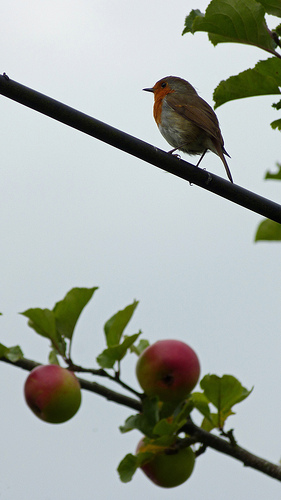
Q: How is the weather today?
A: It is overcast.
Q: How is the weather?
A: It is overcast.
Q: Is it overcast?
A: Yes, it is overcast.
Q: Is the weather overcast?
A: Yes, it is overcast.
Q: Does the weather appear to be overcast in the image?
A: Yes, it is overcast.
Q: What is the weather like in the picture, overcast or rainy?
A: It is overcast.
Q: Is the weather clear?
A: No, it is overcast.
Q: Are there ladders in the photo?
A: No, there are no ladders.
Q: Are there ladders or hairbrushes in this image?
A: No, there are no ladders or hairbrushes.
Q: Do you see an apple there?
A: Yes, there are apples.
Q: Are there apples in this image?
A: Yes, there are apples.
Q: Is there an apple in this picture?
A: Yes, there are apples.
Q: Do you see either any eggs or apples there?
A: Yes, there are apples.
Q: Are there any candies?
A: No, there are no candies.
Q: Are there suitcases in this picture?
A: No, there are no suitcases.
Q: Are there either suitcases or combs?
A: No, there are no suitcases or combs.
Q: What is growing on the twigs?
A: The leaves are growing on the twigs.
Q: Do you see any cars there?
A: No, there are no cars.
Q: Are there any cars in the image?
A: No, there are no cars.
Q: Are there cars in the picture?
A: No, there are no cars.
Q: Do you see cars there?
A: No, there are no cars.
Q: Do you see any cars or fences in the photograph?
A: No, there are no cars or fences.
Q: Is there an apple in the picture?
A: Yes, there are apples.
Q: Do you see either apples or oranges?
A: Yes, there are apples.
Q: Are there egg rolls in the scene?
A: No, there are no egg rolls.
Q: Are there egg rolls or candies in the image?
A: No, there are no egg rolls or candies.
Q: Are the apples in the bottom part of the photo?
A: Yes, the apples are in the bottom of the image.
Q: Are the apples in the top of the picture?
A: No, the apples are in the bottom of the image.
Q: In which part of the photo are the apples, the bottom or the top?
A: The apples are in the bottom of the image.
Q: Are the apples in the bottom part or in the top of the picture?
A: The apples are in the bottom of the image.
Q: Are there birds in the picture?
A: Yes, there is a bird.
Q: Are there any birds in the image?
A: Yes, there is a bird.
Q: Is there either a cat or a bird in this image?
A: Yes, there is a bird.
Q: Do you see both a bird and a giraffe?
A: No, there is a bird but no giraffes.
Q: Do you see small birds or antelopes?
A: Yes, there is a small bird.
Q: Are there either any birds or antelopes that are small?
A: Yes, the bird is small.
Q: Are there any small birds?
A: Yes, there is a small bird.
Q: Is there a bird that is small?
A: Yes, there is a bird that is small.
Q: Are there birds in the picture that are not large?
A: Yes, there is a small bird.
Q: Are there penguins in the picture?
A: No, there are no penguins.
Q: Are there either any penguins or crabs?
A: No, there are no penguins or crabs.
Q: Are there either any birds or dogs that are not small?
A: No, there is a bird but it is small.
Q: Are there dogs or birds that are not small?
A: No, there is a bird but it is small.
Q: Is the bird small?
A: Yes, the bird is small.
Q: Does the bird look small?
A: Yes, the bird is small.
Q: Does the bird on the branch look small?
A: Yes, the bird is small.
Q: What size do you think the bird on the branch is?
A: The bird is small.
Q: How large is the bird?
A: The bird is small.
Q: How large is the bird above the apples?
A: The bird is small.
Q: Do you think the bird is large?
A: No, the bird is small.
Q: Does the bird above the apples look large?
A: No, the bird is small.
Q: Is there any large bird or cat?
A: No, there is a bird but it is small.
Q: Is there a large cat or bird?
A: No, there is a bird but it is small.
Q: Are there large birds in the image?
A: No, there is a bird but it is small.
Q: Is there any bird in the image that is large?
A: No, there is a bird but it is small.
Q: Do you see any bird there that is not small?
A: No, there is a bird but it is small.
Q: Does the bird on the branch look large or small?
A: The bird is small.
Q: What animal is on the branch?
A: The bird is on the branch.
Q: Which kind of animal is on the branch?
A: The animal is a bird.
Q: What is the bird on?
A: The bird is on the branch.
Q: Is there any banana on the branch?
A: No, there is a bird on the branch.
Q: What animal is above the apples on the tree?
A: The animal is a bird.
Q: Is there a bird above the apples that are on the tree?
A: Yes, there is a bird above the apples.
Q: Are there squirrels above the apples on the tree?
A: No, there is a bird above the apples.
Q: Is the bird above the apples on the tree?
A: Yes, the bird is above the apples.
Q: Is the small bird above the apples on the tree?
A: Yes, the bird is above the apples.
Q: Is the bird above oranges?
A: No, the bird is above the apples.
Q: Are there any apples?
A: Yes, there are apples.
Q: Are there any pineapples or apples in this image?
A: Yes, there are apples.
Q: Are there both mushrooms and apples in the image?
A: No, there are apples but no mushrooms.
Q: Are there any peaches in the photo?
A: No, there are no peaches.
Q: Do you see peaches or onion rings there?
A: No, there are no peaches or onion rings.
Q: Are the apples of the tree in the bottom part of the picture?
A: Yes, the apples are in the bottom of the image.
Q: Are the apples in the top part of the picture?
A: No, the apples are in the bottom of the image.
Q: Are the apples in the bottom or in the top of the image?
A: The apples are in the bottom of the image.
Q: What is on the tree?
A: The apples are on the tree.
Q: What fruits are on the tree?
A: The fruits are apples.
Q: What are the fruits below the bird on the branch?
A: The fruits are apples.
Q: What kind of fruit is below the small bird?
A: The fruits are apples.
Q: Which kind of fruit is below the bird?
A: The fruits are apples.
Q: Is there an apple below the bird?
A: Yes, there are apples below the bird.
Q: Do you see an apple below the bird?
A: Yes, there are apples below the bird.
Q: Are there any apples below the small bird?
A: Yes, there are apples below the bird.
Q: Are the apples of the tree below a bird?
A: Yes, the apples are below a bird.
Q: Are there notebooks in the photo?
A: No, there are no notebooks.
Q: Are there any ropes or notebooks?
A: No, there are no notebooks or ropes.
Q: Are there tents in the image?
A: No, there are no tents.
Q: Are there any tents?
A: No, there are no tents.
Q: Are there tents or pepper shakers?
A: No, there are no tents or pepper shakers.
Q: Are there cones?
A: No, there are no cones.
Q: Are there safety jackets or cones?
A: No, there are no cones or safety jackets.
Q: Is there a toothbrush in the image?
A: No, there are no toothbrushes.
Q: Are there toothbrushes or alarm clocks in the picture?
A: No, there are no toothbrushes or alarm clocks.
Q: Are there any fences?
A: No, there are no fences.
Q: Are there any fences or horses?
A: No, there are no fences or horses.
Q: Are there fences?
A: No, there are no fences.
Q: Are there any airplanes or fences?
A: No, there are no fences or airplanes.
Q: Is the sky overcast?
A: Yes, the sky is overcast.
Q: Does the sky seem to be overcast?
A: Yes, the sky is overcast.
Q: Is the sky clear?
A: No, the sky is overcast.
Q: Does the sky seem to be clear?
A: No, the sky is overcast.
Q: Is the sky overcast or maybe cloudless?
A: The sky is overcast.